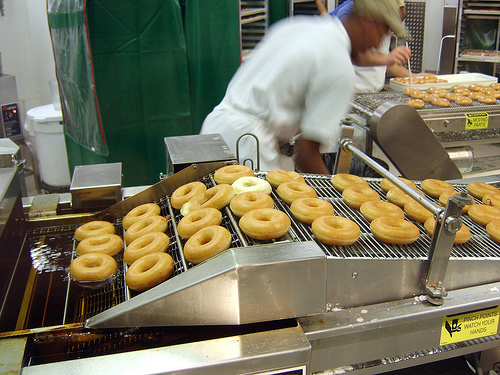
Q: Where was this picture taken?
A: The factory.